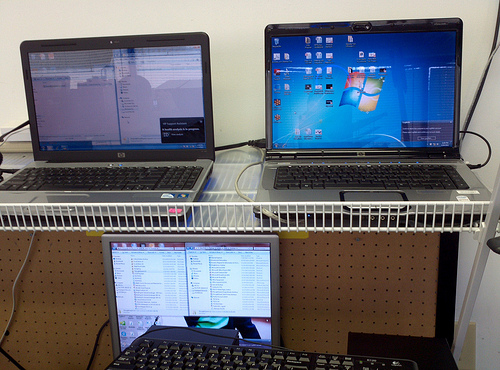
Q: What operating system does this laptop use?
A: Windows.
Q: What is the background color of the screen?
A: Blue.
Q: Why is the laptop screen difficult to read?
A: Glare.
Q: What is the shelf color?
A: White.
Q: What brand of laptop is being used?
A: Hewlett Packard.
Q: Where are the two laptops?
A: On the shelf.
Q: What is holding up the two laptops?
A: A shelf.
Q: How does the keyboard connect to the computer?
A: With a cord.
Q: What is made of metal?
A: The shelf.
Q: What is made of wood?
A: The pegboard.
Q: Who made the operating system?
A: Microsoft.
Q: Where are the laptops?
A: On a shelf.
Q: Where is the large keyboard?
A: On the bottom shelf.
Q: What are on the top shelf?
A: Two laptops.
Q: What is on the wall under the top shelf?
A: Brown peg board.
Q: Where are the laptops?
A: On shelves.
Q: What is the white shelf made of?
A: Metal.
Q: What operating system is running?
A: Windows.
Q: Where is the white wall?
A: Behind the shelf.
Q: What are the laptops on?
A: Racks.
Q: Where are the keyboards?
A: On the laptops.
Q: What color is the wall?
A: White.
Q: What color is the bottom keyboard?
A: Black.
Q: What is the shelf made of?
A: Wire.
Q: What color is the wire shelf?
A: White.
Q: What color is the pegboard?
A: Brown.